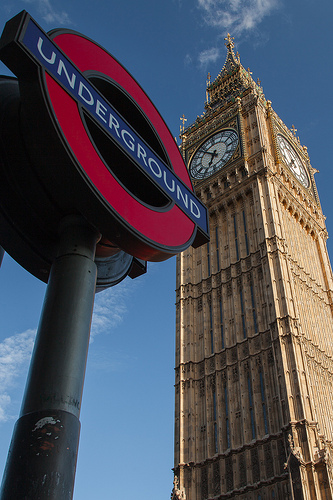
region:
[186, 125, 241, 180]
White clock face on side of tower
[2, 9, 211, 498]
Large red round sign on pole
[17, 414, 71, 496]
Worn spot on sign pole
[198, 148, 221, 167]
Black hands on clock face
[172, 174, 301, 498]
Grooves on side of tower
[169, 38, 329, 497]
this is a tall tower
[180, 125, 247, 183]
this is a clock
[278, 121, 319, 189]
this is a clock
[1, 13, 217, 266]
this is a sign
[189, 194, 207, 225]
a letter on the sign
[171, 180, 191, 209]
a letter on the sign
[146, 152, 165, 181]
a letter on the sign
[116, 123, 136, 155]
a letter on the sign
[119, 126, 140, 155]
a letter on the sign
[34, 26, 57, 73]
This is a letter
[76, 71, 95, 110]
This is a letter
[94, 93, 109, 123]
This is a letter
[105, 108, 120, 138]
This is a letter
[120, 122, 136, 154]
This is a letter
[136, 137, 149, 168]
This is a letter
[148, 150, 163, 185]
This is a letter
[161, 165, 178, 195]
This is a letter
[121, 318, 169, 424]
Blue clear skies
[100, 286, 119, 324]
White clouds in the skies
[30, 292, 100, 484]
a metal pole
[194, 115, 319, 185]
Two clocks on the building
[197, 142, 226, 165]
Arms on the clock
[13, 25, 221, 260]
this is a sign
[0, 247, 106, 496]
this is a sign post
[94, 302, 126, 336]
this is a cloud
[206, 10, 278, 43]
this is a cloud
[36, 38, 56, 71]
a letter on the sign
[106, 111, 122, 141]
a letter on the sign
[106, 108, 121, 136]
a letter on the sign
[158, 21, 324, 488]
this is a tower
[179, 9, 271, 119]
steeple on the tower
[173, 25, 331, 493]
a large tan clock tower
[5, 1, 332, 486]
a sky with clouds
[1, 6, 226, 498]
a large sign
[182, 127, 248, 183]
a black white clock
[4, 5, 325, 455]
a scene during the day time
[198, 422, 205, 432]
a window on a building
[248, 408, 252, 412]
a window on a building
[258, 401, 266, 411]
a window on a building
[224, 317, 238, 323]
a window on a building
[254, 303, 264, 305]
a window on a building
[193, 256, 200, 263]
a window on a building